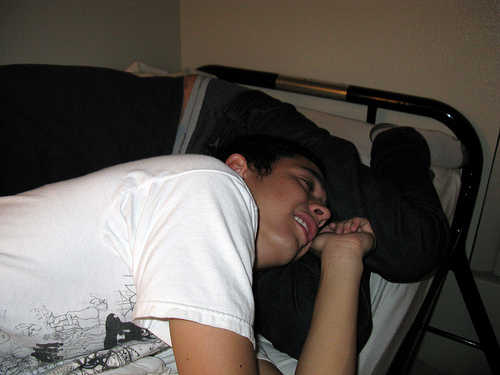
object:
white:
[0, 153, 257, 374]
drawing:
[0, 274, 172, 375]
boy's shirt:
[0, 154, 259, 375]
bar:
[197, 64, 500, 375]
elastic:
[173, 76, 213, 156]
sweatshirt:
[0, 63, 184, 197]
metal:
[194, 63, 500, 375]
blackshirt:
[0, 63, 182, 197]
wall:
[0, 0, 500, 373]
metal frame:
[196, 64, 500, 375]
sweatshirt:
[209, 89, 452, 361]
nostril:
[314, 209, 325, 216]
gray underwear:
[171, 74, 252, 155]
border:
[172, 76, 197, 155]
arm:
[166, 222, 364, 375]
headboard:
[181, 74, 465, 375]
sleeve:
[131, 170, 255, 351]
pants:
[202, 91, 453, 362]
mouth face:
[246, 152, 330, 262]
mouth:
[292, 212, 316, 247]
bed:
[0, 64, 500, 375]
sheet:
[258, 106, 461, 375]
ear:
[225, 154, 247, 180]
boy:
[0, 136, 373, 375]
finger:
[319, 217, 373, 234]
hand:
[310, 217, 377, 252]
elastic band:
[172, 75, 212, 156]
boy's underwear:
[172, 72, 249, 155]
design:
[0, 275, 169, 375]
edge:
[132, 301, 256, 349]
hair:
[214, 134, 328, 181]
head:
[215, 145, 330, 269]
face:
[253, 156, 330, 265]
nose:
[309, 199, 331, 227]